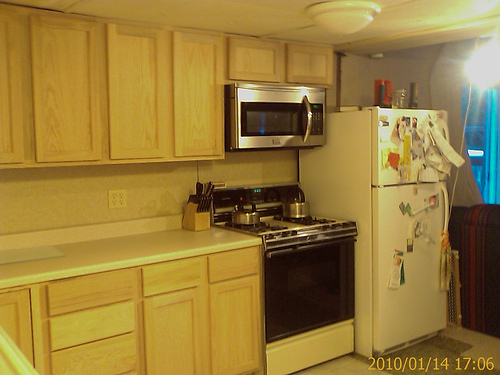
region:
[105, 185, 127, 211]
socket is on the wall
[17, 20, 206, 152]
the cabinets are wooden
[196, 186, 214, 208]
knives are in the knife rack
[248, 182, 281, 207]
timer is on the oven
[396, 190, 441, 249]
stickers are on the fridge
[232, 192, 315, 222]
two pots are on the cooker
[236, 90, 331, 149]
the microwave is above the cooker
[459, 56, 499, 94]
light is coming through the window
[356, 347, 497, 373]
photo was taken in 20.10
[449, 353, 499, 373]
the photo was taken at 17.06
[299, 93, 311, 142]
The door handle of the microwave.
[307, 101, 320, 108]
The time display on the microwave.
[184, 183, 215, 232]
The set of knives on the counter.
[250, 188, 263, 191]
The time display on the stove.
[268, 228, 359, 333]
The oven door of the stove.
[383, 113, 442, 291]
The magnets on the fridge door.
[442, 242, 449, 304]
The towel hanging from the handle of the fridge door.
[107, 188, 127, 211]
The electrical socket above the counter.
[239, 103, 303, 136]
The window of the microwave door.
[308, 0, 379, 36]
The light on the ceiling.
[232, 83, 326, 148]
The microwave above the stove.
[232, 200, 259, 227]
The kettle on the left.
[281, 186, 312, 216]
The kettle on the right.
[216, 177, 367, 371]
The stove below the microwave.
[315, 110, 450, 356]
The refrigerator next to the stove.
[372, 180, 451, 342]
The door of the fridge.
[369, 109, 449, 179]
The freezer door of the fridge.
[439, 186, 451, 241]
The door handle of the fridge.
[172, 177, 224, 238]
Knife block on the counter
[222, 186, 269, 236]
Teapot on the stove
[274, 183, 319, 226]
Teapot on the stove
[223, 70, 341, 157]
Microwave over the stove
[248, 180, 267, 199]
Clock display on the stove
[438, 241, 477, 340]
Gate on side of fridge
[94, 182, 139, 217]
Socket on the wall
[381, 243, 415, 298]
Paper on the fridge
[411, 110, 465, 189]
Paper hanging on fridge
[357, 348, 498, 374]
Time and date stamp in corner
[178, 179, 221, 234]
a knife block with knives in it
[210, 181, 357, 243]
a stove with two tea kettles on it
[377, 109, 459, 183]
papers on a freezer door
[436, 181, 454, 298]
refrigerator handle with a towel hanging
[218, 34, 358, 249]
microwave above the stove top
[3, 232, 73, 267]
a glass cutting board on the counter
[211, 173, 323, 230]
two metal tea kettles with black handles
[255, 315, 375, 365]
storage drawer below the oven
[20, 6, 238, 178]
wood kitchen cabinets on the wall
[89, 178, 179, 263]
an electrical outlet on the wall